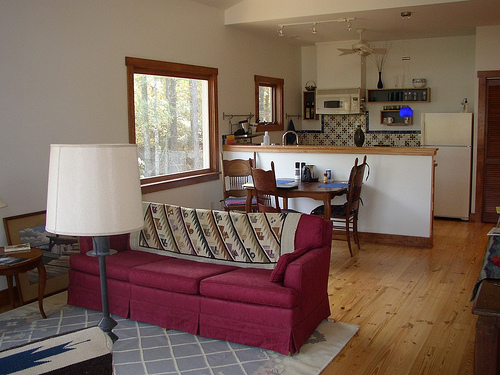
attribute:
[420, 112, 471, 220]
refrigerator — white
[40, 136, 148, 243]
lamp shade — white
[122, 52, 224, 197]
window — brown, framed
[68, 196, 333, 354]
couch — pink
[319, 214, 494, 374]
hardwood floor — light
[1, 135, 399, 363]
sofa — red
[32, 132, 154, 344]
lamp — floor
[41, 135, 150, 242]
shade — cream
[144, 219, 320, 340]
couch — red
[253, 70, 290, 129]
window — small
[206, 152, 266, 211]
chair — empty, brown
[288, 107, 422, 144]
backsplash — tiled